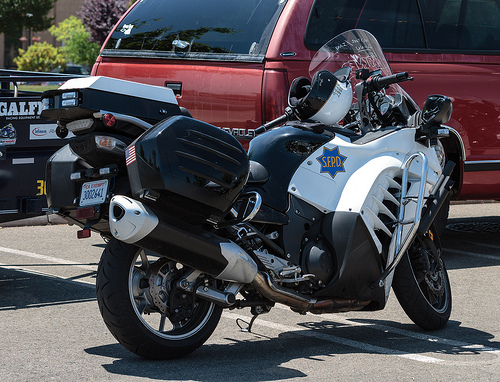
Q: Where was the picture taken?
A: Parking lot.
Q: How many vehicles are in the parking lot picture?
A: Two.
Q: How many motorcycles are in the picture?
A: 1.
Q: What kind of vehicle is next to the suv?
A: Motorcycle.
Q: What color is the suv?
A: Red.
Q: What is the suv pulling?
A: Trailer.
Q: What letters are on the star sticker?
A: S.F.P.D.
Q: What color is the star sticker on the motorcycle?
A: Blue and yellow.